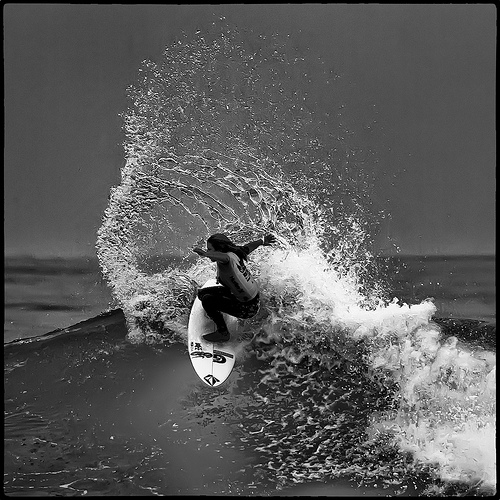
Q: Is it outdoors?
A: Yes, it is outdoors.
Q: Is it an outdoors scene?
A: Yes, it is outdoors.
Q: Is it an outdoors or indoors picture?
A: It is outdoors.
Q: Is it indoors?
A: No, it is outdoors.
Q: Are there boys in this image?
A: No, there are no boys.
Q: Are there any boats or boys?
A: No, there are no boys or boats.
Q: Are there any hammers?
A: No, there are no hammers.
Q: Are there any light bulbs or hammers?
A: No, there are no hammers or light bulbs.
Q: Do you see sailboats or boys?
A: No, there are no boys or sailboats.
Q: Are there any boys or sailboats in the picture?
A: No, there are no boys or sailboats.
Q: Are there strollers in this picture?
A: No, there are no strollers.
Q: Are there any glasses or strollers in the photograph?
A: No, there are no strollers or glasses.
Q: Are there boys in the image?
A: No, there are no boys.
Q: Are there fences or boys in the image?
A: No, there are no boys or fences.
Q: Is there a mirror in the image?
A: No, there are no mirrors.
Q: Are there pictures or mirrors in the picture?
A: No, there are no mirrors or pictures.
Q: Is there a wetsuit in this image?
A: Yes, there is a wetsuit.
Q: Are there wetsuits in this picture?
A: Yes, there is a wetsuit.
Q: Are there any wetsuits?
A: Yes, there is a wetsuit.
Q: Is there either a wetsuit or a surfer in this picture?
A: Yes, there is a wetsuit.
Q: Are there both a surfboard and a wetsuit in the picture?
A: Yes, there are both a wetsuit and a surfboard.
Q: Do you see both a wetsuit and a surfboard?
A: Yes, there are both a wetsuit and a surfboard.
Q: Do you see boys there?
A: No, there are no boys.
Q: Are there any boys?
A: No, there are no boys.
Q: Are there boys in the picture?
A: No, there are no boys.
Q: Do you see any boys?
A: No, there are no boys.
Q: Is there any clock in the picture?
A: No, there are no clocks.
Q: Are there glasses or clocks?
A: No, there are no clocks or glasses.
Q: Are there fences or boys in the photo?
A: No, there are no fences or boys.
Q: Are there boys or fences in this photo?
A: No, there are no fences or boys.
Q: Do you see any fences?
A: No, there are no fences.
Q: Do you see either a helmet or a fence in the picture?
A: No, there are no fences or helmets.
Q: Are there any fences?
A: No, there are no fences.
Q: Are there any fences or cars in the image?
A: No, there are no fences or cars.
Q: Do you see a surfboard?
A: Yes, there is a surfboard.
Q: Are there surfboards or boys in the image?
A: Yes, there is a surfboard.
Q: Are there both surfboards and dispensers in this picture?
A: No, there is a surfboard but no dispensers.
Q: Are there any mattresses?
A: No, there are no mattresses.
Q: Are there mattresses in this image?
A: No, there are no mattresses.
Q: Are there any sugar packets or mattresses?
A: No, there are no mattresses or sugar packets.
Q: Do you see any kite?
A: No, there are no kites.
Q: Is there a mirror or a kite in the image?
A: No, there are no kites or mirrors.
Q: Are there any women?
A: Yes, there is a woman.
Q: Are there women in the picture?
A: Yes, there is a woman.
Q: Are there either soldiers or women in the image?
A: Yes, there is a woman.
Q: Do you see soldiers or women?
A: Yes, there is a woman.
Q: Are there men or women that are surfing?
A: Yes, the woman is surfing.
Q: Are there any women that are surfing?
A: Yes, there is a woman that is surfing.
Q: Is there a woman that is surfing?
A: Yes, there is a woman that is surfing.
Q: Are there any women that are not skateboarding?
A: Yes, there is a woman that is surfing.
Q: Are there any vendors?
A: No, there are no vendors.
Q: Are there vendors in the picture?
A: No, there are no vendors.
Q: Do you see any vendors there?
A: No, there are no vendors.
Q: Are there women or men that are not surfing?
A: No, there is a woman but she is surfing.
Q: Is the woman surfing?
A: Yes, the woman is surfing.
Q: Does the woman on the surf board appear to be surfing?
A: Yes, the woman is surfing.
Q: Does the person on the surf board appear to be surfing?
A: Yes, the woman is surfing.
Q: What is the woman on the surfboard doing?
A: The woman is surfing.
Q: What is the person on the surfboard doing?
A: The woman is surfing.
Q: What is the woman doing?
A: The woman is surfing.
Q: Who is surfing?
A: The woman is surfing.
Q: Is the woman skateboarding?
A: No, the woman is surfing.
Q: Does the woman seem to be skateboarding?
A: No, the woman is surfing.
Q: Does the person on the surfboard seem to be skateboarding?
A: No, the woman is surfing.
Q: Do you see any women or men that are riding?
A: No, there is a woman but she is surfing.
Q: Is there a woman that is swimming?
A: No, there is a woman but she is surfing.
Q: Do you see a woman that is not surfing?
A: No, there is a woman but she is surfing.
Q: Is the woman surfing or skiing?
A: The woman is surfing.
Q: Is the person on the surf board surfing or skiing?
A: The woman is surfing.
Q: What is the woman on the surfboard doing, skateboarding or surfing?
A: The woman is surfing.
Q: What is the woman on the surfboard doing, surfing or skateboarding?
A: The woman is surfing.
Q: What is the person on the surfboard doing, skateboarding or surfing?
A: The woman is surfing.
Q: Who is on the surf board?
A: The woman is on the surf board.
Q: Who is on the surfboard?
A: The woman is on the surf board.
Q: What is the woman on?
A: The woman is on the surfboard.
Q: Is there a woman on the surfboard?
A: Yes, there is a woman on the surfboard.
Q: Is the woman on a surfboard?
A: Yes, the woman is on a surfboard.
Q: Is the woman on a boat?
A: No, the woman is on a surfboard.